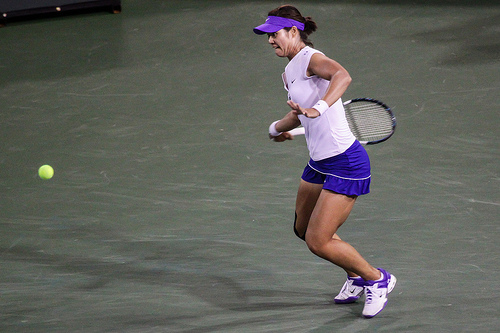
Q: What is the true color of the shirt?
A: White.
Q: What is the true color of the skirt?
A: Blue.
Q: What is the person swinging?
A: Racket.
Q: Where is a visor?
A: On woman's head.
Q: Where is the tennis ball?
A: In the air.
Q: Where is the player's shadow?
A: On the court.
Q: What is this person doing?
A: Playing tennis.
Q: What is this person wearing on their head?
A: A visor.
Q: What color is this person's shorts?
A: Blue.